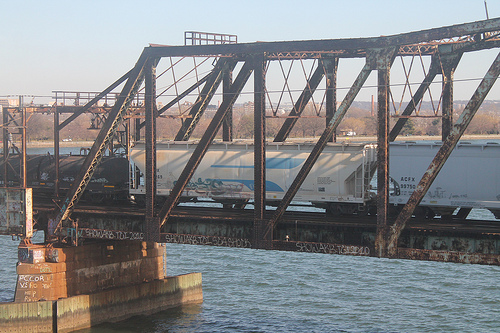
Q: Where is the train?
A: On a bridge.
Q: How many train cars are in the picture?
A: Three.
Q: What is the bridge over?
A: Water.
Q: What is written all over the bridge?
A: Graffiti.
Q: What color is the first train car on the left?
A: Black.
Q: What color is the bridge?
A: Brown.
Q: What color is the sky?
A: Blue.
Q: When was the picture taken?
A: Daytime.